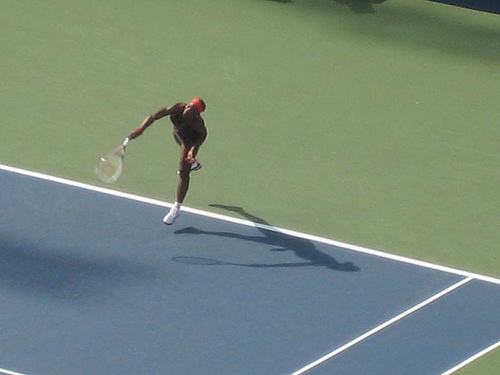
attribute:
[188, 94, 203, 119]
headband — orange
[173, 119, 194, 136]
shirt — Black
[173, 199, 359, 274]
shadow — black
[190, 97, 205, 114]
headband — Worn, Red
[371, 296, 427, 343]
line — white 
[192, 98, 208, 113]
headband — orange 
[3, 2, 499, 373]
court — blue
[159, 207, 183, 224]
sneakers — white